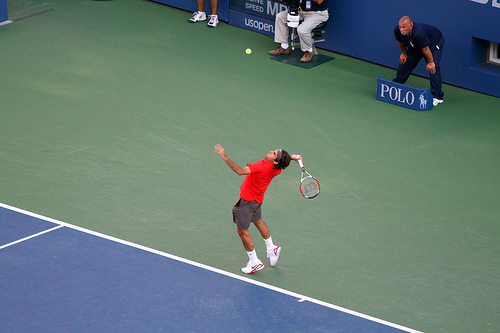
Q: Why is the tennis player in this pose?
A: Ready hit ball.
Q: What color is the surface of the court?
A: Green.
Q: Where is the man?
A: On a tennis court.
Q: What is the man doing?
A: Playing tennis.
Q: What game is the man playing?
A: Tennis.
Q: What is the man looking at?
A: A tennis ball.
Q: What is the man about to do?
A: Hit a tennis ball.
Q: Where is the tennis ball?
A: In the air.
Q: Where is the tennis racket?
A: In the man's hand.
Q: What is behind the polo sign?
A: A man.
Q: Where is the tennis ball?
A: In the air.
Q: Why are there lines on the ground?
A: To separate parts of a tennis court.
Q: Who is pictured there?
A: Tennis player.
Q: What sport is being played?
A: Tennis.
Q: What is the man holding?
A: Racket.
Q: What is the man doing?
A: Jumping.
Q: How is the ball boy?
A: Bent down.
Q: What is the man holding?
A: Racket.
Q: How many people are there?
A: Four.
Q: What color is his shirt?
A: Bright red.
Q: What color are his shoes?
A: Red and white.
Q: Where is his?
A: Tennis court.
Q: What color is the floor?
A: Green and blue.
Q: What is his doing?
A: Getting ready to hit a ball.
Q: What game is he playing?
A: Tennis.